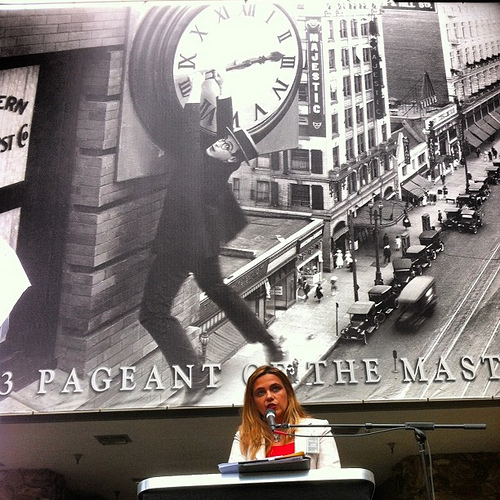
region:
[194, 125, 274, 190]
the head of a man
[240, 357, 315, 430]
the head of a woman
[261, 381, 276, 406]
the nose of a woman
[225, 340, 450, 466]
a woman wearing a white jacket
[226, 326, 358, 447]
a woman talking into a micro phone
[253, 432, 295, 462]
a woman wearing a red shirt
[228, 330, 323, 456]
the hair of a woman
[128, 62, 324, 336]
a man wearing a suit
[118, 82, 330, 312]
a man hanging from a clock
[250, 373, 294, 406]
the eyes of a woman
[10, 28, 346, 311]
the is a person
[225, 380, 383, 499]
the woman is talking into the microphone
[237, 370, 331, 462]
the woman has blonde hair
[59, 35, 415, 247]
this photo is in black and white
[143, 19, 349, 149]
this is a clock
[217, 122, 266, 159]
the man has glasses on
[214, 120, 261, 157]
the man has a hat on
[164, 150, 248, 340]
the man is wearing a dark suit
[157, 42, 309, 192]
the man is hanging from the clock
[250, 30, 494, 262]
this is a city setting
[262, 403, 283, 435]
Microphone in the forefront.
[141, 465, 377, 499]
Silver podium in the forefront.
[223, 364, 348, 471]
woman speaking in the microphone.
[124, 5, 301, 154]
Clock on the wall screen.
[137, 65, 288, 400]
Man hanging from clock hands.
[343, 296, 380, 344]
Car on the street.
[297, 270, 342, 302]
People walking on the street.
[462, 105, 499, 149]
Awnings on the buildings.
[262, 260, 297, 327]
Store front of the building.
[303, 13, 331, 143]
Sign on the side of the building.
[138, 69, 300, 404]
man in black suit and hat hanging from clock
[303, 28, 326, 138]
MAJESTIC sign on side of building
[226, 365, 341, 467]
woman in red shirt and white jacket speaking into microphone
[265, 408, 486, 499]
black microphone and stand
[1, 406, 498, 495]
white ceiling with two vents and two fire sprinklers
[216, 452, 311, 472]
file folder and papers on podium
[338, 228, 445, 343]
line of old vehicles parked on side of road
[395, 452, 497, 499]
stone pillar holding up ceiling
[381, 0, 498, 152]
large building in projection above woman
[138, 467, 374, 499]
silver podium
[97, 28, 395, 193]
a clock on a building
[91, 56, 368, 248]
a woman hanging from a clcok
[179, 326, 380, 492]
a person standing at a podeum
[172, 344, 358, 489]
a woman standing at a podiam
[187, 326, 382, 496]
a perosn with straight hair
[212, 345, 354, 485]
a woman with straight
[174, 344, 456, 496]
a woman with blonde hiar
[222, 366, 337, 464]
a woman talkign into microphone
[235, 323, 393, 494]
a woman wearing a whtie jacket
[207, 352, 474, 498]
a woman that is talking